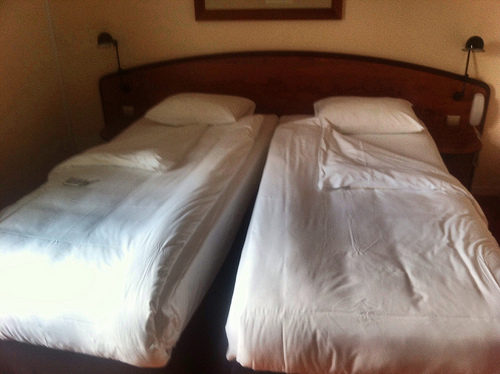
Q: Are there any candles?
A: No, there are no candles.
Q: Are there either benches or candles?
A: No, there are no candles or benches.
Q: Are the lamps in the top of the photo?
A: Yes, the lamps are in the top of the image.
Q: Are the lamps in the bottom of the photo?
A: No, the lamps are in the top of the image.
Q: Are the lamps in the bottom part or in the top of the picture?
A: The lamps are in the top of the image.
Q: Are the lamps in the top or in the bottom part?
A: The lamps are in the top of the image.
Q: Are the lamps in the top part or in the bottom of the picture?
A: The lamps are in the top of the image.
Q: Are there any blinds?
A: No, there are no blinds.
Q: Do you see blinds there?
A: No, there are no blinds.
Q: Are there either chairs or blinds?
A: No, there are no blinds or chairs.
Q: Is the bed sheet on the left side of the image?
A: No, the bed sheet is on the right of the image.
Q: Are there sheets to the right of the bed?
A: Yes, there is a sheet to the right of the bed.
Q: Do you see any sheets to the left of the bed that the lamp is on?
A: No, the sheet is to the right of the bed.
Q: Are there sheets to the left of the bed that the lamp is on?
A: No, the sheet is to the right of the bed.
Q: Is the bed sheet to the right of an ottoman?
A: No, the bed sheet is to the right of a bed.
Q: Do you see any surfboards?
A: No, there are no surfboards.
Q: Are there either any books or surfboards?
A: No, there are no surfboards or books.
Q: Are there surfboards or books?
A: No, there are no surfboards or books.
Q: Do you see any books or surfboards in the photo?
A: No, there are no surfboards or books.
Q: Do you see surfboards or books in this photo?
A: No, there are no surfboards or books.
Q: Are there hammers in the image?
A: No, there are no hammers.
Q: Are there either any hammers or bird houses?
A: No, there are no hammers or bird houses.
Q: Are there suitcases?
A: No, there are no suitcases.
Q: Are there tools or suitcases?
A: No, there are no suitcases or tools.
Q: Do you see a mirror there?
A: No, there are no mirrors.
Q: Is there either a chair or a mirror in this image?
A: No, there are no mirrors or chairs.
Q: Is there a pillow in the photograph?
A: Yes, there is a pillow.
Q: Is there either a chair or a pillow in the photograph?
A: Yes, there is a pillow.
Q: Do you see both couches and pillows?
A: No, there is a pillow but no couches.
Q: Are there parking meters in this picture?
A: No, there are no parking meters.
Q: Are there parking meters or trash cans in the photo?
A: No, there are no parking meters or trash cans.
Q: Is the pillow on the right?
A: Yes, the pillow is on the right of the image.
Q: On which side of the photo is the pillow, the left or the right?
A: The pillow is on the right of the image.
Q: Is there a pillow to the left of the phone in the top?
A: Yes, there is a pillow to the left of the telephone.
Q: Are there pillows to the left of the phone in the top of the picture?
A: Yes, there is a pillow to the left of the telephone.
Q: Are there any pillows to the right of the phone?
A: No, the pillow is to the left of the phone.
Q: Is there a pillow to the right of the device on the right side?
A: No, the pillow is to the left of the phone.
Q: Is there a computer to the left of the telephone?
A: No, there is a pillow to the left of the telephone.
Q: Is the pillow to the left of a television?
A: No, the pillow is to the left of the telephone.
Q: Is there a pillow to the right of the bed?
A: Yes, there is a pillow to the right of the bed.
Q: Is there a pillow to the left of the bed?
A: No, the pillow is to the right of the bed.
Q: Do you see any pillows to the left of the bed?
A: No, the pillow is to the right of the bed.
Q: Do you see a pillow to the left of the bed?
A: No, the pillow is to the right of the bed.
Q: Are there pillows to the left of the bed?
A: No, the pillow is to the right of the bed.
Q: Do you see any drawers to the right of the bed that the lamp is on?
A: No, there is a pillow to the right of the bed.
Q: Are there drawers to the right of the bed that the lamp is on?
A: No, there is a pillow to the right of the bed.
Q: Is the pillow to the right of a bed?
A: Yes, the pillow is to the right of a bed.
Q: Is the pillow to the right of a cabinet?
A: No, the pillow is to the right of a bed.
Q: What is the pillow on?
A: The pillow is on the bed.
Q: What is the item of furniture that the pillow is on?
A: The piece of furniture is a bed.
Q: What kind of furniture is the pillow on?
A: The pillow is on the bed.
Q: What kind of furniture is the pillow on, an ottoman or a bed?
A: The pillow is on a bed.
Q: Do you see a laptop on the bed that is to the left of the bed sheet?
A: No, there is a pillow on the bed.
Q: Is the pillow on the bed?
A: Yes, the pillow is on the bed.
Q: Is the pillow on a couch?
A: No, the pillow is on the bed.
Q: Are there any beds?
A: Yes, there is a bed.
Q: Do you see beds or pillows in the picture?
A: Yes, there is a bed.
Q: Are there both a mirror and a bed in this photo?
A: No, there is a bed but no mirrors.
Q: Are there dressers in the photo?
A: No, there are no dressers.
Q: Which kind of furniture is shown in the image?
A: The furniture is a bed.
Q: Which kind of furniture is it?
A: The piece of furniture is a bed.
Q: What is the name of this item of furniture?
A: This is a bed.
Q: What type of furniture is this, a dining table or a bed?
A: This is a bed.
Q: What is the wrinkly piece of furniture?
A: The piece of furniture is a bed.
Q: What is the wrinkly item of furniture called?
A: The piece of furniture is a bed.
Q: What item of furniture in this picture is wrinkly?
A: The piece of furniture is a bed.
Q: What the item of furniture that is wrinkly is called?
A: The piece of furniture is a bed.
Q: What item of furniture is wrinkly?
A: The piece of furniture is a bed.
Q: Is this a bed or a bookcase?
A: This is a bed.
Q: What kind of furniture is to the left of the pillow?
A: The piece of furniture is a bed.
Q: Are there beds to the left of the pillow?
A: Yes, there is a bed to the left of the pillow.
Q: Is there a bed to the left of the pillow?
A: Yes, there is a bed to the left of the pillow.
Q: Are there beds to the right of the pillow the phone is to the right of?
A: No, the bed is to the left of the pillow.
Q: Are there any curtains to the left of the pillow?
A: No, there is a bed to the left of the pillow.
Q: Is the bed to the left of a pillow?
A: Yes, the bed is to the left of a pillow.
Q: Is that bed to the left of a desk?
A: No, the bed is to the left of a pillow.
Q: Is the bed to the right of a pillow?
A: No, the bed is to the left of a pillow.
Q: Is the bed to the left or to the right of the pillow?
A: The bed is to the left of the pillow.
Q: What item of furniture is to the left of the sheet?
A: The piece of furniture is a bed.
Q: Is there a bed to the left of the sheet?
A: Yes, there is a bed to the left of the sheet.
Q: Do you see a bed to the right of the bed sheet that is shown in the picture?
A: No, the bed is to the left of the bed sheet.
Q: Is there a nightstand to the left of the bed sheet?
A: No, there is a bed to the left of the bed sheet.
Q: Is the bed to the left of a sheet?
A: Yes, the bed is to the left of a sheet.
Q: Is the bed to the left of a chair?
A: No, the bed is to the left of a sheet.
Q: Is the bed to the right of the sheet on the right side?
A: No, the bed is to the left of the bed sheet.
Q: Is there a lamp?
A: Yes, there is a lamp.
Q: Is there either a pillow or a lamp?
A: Yes, there is a lamp.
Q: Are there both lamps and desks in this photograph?
A: No, there is a lamp but no desks.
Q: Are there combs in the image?
A: No, there are no combs.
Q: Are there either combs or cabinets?
A: No, there are no combs or cabinets.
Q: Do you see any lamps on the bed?
A: Yes, there is a lamp on the bed.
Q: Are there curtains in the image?
A: No, there are no curtains.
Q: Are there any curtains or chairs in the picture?
A: No, there are no curtains or chairs.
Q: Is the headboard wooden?
A: Yes, the headboard is wooden.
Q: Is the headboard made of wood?
A: Yes, the headboard is made of wood.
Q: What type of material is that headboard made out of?
A: The headboard is made of wood.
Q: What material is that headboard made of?
A: The headboard is made of wood.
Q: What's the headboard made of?
A: The headboard is made of wood.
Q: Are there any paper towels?
A: No, there are no paper towels.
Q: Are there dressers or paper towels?
A: No, there are no paper towels or dressers.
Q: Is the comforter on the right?
A: No, the comforter is on the left of the image.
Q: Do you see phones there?
A: Yes, there is a phone.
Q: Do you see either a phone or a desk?
A: Yes, there is a phone.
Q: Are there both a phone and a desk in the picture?
A: No, there is a phone but no desks.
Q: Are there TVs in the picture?
A: No, there are no tvs.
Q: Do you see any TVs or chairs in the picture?
A: No, there are no TVs or chairs.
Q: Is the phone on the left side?
A: No, the phone is on the right of the image.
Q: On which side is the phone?
A: The phone is on the right of the image.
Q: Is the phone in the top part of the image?
A: Yes, the phone is in the top of the image.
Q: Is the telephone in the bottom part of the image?
A: No, the telephone is in the top of the image.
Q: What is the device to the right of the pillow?
A: The device is a phone.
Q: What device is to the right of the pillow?
A: The device is a phone.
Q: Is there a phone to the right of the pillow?
A: Yes, there is a phone to the right of the pillow.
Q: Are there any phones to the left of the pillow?
A: No, the phone is to the right of the pillow.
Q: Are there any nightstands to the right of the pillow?
A: No, there is a phone to the right of the pillow.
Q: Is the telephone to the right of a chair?
A: No, the telephone is to the right of the pillow.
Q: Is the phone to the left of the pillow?
A: No, the phone is to the right of the pillow.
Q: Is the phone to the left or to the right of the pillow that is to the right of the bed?
A: The phone is to the right of the pillow.